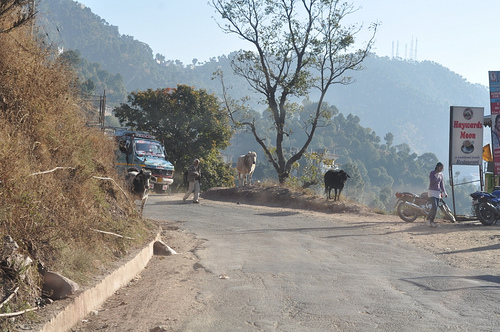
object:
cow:
[324, 169, 351, 202]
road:
[65, 194, 497, 332]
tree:
[208, 0, 382, 187]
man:
[426, 162, 448, 228]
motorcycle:
[395, 192, 457, 224]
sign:
[450, 105, 484, 221]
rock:
[332, 205, 351, 213]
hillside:
[0, 2, 160, 280]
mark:
[463, 108, 474, 121]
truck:
[113, 130, 176, 197]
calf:
[236, 151, 257, 187]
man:
[183, 159, 202, 204]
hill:
[234, 49, 493, 215]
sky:
[69, 0, 499, 88]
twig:
[359, 18, 383, 63]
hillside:
[354, 177, 500, 208]